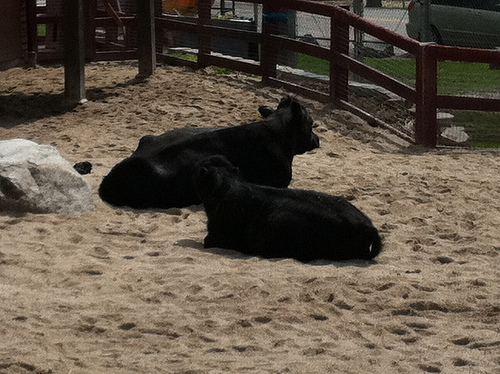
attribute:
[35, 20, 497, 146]
grass — green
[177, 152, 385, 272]
cow — black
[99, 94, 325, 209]
cow — black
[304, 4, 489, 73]
van — mini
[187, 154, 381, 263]
cow — black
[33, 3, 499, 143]
fence — red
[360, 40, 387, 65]
net — metal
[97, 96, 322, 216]
black cow — big